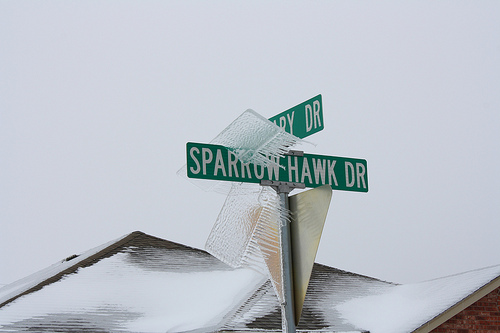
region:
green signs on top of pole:
[178, 90, 374, 196]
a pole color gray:
[270, 180, 297, 325]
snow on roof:
[0, 225, 496, 330]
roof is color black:
[4, 225, 499, 332]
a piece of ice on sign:
[165, 98, 303, 188]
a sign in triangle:
[238, 178, 339, 328]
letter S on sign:
[186, 144, 202, 176]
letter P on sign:
[199, 142, 214, 178]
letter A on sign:
[211, 143, 230, 180]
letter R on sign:
[310, 97, 327, 129]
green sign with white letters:
[185, 132, 376, 202]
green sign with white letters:
[236, 103, 351, 135]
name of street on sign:
[184, 142, 367, 189]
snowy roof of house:
[316, 250, 438, 330]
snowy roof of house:
[7, 243, 126, 290]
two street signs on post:
[176, 73, 389, 205]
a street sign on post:
[236, 88, 345, 141]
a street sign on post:
[181, 135, 383, 199]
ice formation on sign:
[219, 169, 285, 270]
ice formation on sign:
[201, 103, 314, 173]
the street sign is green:
[178, 139, 385, 196]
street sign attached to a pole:
[177, 125, 408, 328]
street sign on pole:
[164, 138, 366, 198]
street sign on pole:
[239, 100, 321, 142]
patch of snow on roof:
[166, 288, 187, 300]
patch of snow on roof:
[397, 298, 419, 315]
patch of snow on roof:
[86, 272, 110, 289]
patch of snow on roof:
[438, 281, 464, 297]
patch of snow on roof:
[368, 312, 387, 326]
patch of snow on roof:
[113, 275, 136, 290]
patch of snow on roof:
[146, 311, 167, 323]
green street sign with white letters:
[181, 139, 374, 200]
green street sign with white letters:
[238, 90, 335, 145]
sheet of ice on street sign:
[199, 178, 271, 267]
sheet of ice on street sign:
[201, 106, 308, 168]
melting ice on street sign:
[191, 179, 286, 266]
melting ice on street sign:
[203, 106, 305, 179]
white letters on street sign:
[185, 146, 367, 193]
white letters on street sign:
[271, 100, 322, 134]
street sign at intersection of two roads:
[168, 93, 380, 197]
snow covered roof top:
[11, 227, 238, 330]